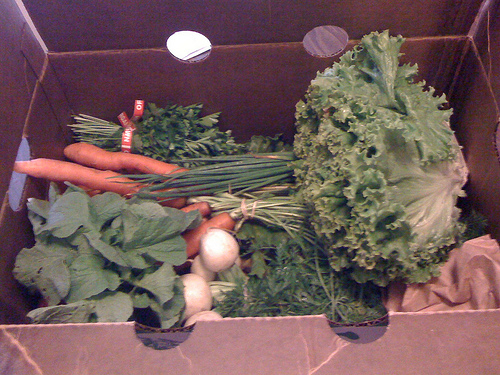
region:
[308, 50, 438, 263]
this is a broccoli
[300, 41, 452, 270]
the broccoli is fresh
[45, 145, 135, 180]
these are two carrots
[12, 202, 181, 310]
these are the kales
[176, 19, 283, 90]
this is a carton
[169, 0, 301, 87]
the carton is open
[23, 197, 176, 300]
the kales are fresh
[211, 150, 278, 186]
these are onions in the middle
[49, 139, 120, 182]
the carrots are orange in color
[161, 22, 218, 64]
this is a hole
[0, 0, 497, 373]
Vegetables in a cardboard box.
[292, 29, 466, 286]
A head of lettuce.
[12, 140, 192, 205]
A few raw carrots.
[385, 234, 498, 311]
Brown paper packing material.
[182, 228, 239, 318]
Four small white onions.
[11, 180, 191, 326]
A leafy green vegetable.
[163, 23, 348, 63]
The cardboard box has holes at the top.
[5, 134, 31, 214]
A handhold for carrying the box.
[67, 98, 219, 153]
The produce is tied with a red band.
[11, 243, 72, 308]
A leaf has holes in it.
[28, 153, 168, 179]
these are some carrots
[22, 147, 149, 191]
the carrots are long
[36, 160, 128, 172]
the carrots are orange in color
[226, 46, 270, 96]
this is a carton box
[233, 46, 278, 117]
the box is brown in color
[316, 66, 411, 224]
these are some vegetables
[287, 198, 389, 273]
the leaves are big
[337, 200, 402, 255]
the leaves are green in color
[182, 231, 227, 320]
these are some onions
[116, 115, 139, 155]
this is a wrap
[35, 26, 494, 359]
a box of vegetables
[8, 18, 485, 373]
a brown box of vegetables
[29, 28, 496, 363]
a cardboard box with vegetables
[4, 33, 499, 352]
a brown cardboard box with vegetables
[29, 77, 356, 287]
carrots in a box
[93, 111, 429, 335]
green onions in a box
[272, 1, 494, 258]
cabbage in a box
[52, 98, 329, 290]
carrots with other vegetables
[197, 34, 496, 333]
cabbage with other vegetables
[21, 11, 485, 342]
vegetables in a brown box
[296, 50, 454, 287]
a head of romaine lettuce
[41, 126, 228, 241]
a bunch of orange carrots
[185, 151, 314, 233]
two bunches of green onions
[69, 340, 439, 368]
a brown cardboard box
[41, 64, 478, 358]
a cardboard box filled with vegetables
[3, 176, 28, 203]
grey surface of the table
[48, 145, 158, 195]
orange skin of the carrots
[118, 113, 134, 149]
white lettering on a red label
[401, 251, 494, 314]
a piece of bunched up brown paper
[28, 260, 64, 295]
caterpillar holes in the leaves